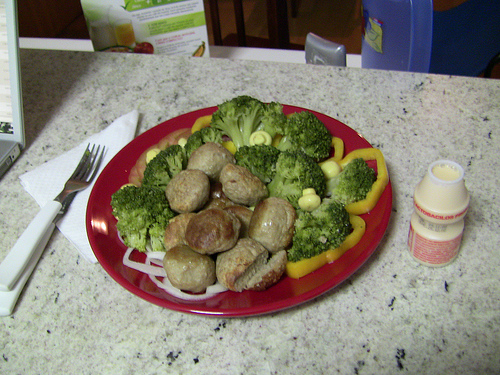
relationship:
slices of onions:
[132, 256, 182, 298] [124, 246, 204, 293]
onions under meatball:
[124, 246, 204, 293] [162, 241, 212, 290]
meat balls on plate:
[159, 138, 296, 294] [83, 95, 393, 315]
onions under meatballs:
[124, 250, 215, 297] [160, 137, 294, 292]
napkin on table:
[16, 104, 144, 264] [7, 47, 480, 367]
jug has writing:
[405, 158, 472, 265] [407, 225, 462, 263]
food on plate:
[108, 91, 387, 291] [83, 95, 393, 315]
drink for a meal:
[404, 152, 472, 268] [86, 92, 396, 319]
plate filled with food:
[83, 95, 393, 315] [108, 91, 387, 291]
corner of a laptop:
[6, 117, 36, 158] [5, 9, 33, 157]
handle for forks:
[0, 199, 63, 292] [6, 140, 105, 293]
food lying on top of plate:
[108, 91, 387, 291] [83, 95, 393, 315]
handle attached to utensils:
[1, 199, 63, 291] [0, 141, 108, 293]